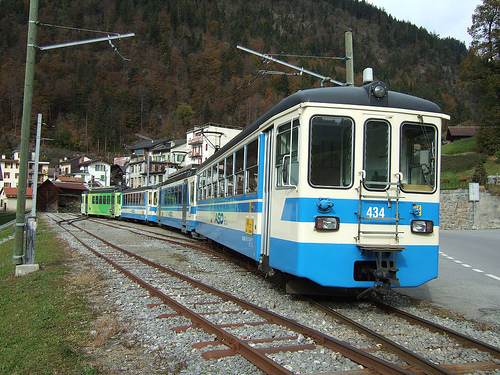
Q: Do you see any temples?
A: No, there are no temples.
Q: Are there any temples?
A: No, there are no temples.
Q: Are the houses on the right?
A: No, the houses are on the left of the image.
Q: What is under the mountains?
A: The houses are under the mountains.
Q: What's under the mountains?
A: The houses are under the mountains.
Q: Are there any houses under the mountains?
A: Yes, there are houses under the mountains.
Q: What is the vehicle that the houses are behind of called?
A: The vehicle is a train.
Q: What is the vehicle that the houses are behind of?
A: The vehicle is a train.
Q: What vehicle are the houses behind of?
A: The houses are behind the train.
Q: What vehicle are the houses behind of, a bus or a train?
A: The houses are behind a train.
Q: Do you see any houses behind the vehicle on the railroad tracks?
A: Yes, there are houses behind the train.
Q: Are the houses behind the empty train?
A: Yes, the houses are behind the train.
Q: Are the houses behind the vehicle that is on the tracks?
A: Yes, the houses are behind the train.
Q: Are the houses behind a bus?
A: No, the houses are behind the train.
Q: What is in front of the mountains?
A: The houses are in front of the mountains.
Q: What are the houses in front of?
A: The houses are in front of the mountains.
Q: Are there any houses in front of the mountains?
A: Yes, there are houses in front of the mountains.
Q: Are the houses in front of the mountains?
A: Yes, the houses are in front of the mountains.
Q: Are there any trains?
A: Yes, there is a train.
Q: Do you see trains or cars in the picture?
A: Yes, there is a train.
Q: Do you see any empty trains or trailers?
A: Yes, there is an empty train.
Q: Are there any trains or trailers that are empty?
A: Yes, the train is empty.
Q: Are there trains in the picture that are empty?
A: Yes, there is an empty train.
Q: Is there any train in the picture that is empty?
A: Yes, there is a train that is empty.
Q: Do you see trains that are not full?
A: Yes, there is a empty train.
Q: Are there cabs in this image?
A: No, there are no cabs.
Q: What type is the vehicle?
A: The vehicle is a train.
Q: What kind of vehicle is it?
A: The vehicle is a train.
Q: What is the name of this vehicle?
A: This is a train.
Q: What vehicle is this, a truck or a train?
A: This is a train.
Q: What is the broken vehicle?
A: The vehicle is a train.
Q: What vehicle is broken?
A: The vehicle is a train.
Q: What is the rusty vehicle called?
A: The vehicle is a train.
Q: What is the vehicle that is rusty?
A: The vehicle is a train.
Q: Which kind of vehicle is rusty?
A: The vehicle is a train.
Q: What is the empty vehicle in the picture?
A: The vehicle is a train.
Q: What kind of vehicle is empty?
A: The vehicle is a train.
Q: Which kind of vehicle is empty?
A: The vehicle is a train.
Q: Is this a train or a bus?
A: This is a train.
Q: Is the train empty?
A: Yes, the train is empty.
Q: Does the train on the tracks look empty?
A: Yes, the train is empty.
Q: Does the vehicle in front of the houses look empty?
A: Yes, the train is empty.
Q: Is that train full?
A: No, the train is empty.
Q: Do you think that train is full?
A: No, the train is empty.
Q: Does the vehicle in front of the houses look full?
A: No, the train is empty.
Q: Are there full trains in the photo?
A: No, there is a train but it is empty.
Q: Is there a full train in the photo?
A: No, there is a train but it is empty.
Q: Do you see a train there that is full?
A: No, there is a train but it is empty.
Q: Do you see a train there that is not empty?
A: No, there is a train but it is empty.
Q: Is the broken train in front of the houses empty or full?
A: The train is empty.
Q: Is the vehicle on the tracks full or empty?
A: The train is empty.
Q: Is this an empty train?
A: Yes, this is an empty train.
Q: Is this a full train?
A: No, this is an empty train.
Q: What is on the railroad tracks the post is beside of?
A: The train is on the railroad tracks.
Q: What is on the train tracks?
A: The train is on the railroad tracks.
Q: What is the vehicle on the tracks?
A: The vehicle is a train.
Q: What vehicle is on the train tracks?
A: The vehicle is a train.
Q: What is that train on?
A: The train is on the railroad tracks.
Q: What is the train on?
A: The train is on the railroad tracks.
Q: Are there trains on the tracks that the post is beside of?
A: Yes, there is a train on the train tracks.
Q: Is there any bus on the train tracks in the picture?
A: No, there is a train on the train tracks.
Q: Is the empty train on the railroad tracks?
A: Yes, the train is on the railroad tracks.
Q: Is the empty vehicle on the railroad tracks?
A: Yes, the train is on the railroad tracks.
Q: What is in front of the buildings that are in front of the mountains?
A: The train is in front of the houses.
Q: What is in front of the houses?
A: The train is in front of the houses.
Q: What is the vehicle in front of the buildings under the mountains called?
A: The vehicle is a train.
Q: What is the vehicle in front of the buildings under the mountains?
A: The vehicle is a train.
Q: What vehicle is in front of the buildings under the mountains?
A: The vehicle is a train.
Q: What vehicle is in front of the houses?
A: The vehicle is a train.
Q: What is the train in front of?
A: The train is in front of the houses.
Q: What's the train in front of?
A: The train is in front of the houses.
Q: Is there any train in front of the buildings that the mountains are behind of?
A: Yes, there is a train in front of the houses.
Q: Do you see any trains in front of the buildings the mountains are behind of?
A: Yes, there is a train in front of the houses.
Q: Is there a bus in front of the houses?
A: No, there is a train in front of the houses.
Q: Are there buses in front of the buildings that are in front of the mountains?
A: No, there is a train in front of the houses.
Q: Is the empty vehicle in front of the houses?
A: Yes, the train is in front of the houses.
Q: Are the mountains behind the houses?
A: Yes, the mountains are behind the houses.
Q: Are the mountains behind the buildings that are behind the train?
A: Yes, the mountains are behind the houses.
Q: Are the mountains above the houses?
A: Yes, the mountains are above the houses.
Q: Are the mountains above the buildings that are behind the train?
A: Yes, the mountains are above the houses.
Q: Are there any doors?
A: Yes, there are doors.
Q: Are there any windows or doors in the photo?
A: Yes, there are doors.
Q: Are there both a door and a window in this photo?
A: Yes, there are both a door and a window.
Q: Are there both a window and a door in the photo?
A: Yes, there are both a door and a window.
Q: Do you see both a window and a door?
A: Yes, there are both a door and a window.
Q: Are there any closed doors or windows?
A: Yes, there are closed doors.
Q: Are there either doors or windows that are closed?
A: Yes, the doors are closed.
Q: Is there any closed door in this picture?
A: Yes, there are closed doors.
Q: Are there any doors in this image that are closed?
A: Yes, there are doors that are closed.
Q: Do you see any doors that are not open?
A: Yes, there are closed doors.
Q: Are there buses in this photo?
A: No, there are no buses.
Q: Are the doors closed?
A: Yes, the doors are closed.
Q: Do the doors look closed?
A: Yes, the doors are closed.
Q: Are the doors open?
A: No, the doors are closed.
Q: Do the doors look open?
A: No, the doors are closed.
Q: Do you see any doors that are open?
A: No, there are doors but they are closed.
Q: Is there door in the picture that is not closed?
A: No, there are doors but they are closed.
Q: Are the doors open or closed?
A: The doors are closed.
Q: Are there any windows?
A: Yes, there are windows.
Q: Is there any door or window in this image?
A: Yes, there are windows.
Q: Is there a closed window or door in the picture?
A: Yes, there are closed windows.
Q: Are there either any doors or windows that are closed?
A: Yes, the windows are closed.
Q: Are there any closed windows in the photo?
A: Yes, there are closed windows.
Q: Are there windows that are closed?
A: Yes, there are windows that are closed.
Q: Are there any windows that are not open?
A: Yes, there are closed windows.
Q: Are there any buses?
A: No, there are no buses.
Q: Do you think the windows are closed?
A: Yes, the windows are closed.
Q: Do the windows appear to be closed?
A: Yes, the windows are closed.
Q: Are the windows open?
A: No, the windows are closed.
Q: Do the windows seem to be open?
A: No, the windows are closed.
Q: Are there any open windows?
A: No, there are windows but they are closed.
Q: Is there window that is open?
A: No, there are windows but they are closed.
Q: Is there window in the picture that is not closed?
A: No, there are windows but they are closed.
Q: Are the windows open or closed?
A: The windows are closed.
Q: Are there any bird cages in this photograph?
A: No, there are no bird cages.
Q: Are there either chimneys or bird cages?
A: No, there are no bird cages or chimneys.